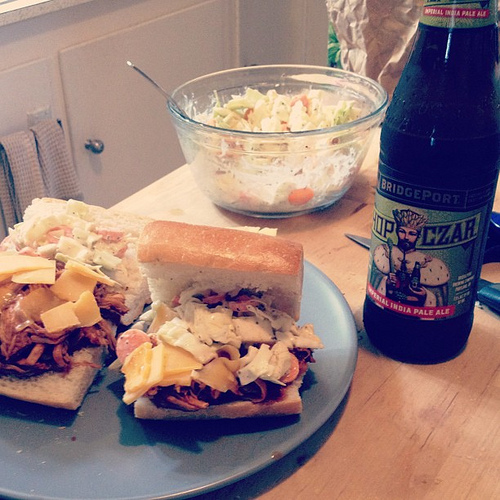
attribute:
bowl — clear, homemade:
[161, 55, 393, 223]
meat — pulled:
[17, 322, 67, 369]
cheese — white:
[112, 333, 209, 405]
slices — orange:
[120, 342, 193, 384]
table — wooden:
[353, 376, 470, 498]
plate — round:
[23, 159, 468, 493]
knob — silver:
[82, 136, 105, 153]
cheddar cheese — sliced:
[124, 350, 198, 387]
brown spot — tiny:
[263, 450, 280, 462]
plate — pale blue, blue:
[0, 254, 361, 499]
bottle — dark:
[359, 2, 496, 365]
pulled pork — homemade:
[1, 238, 324, 400]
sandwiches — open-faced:
[0, 187, 318, 439]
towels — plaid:
[45, 159, 72, 187]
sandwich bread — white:
[131, 213, 309, 325]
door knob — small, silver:
[87, 136, 115, 164]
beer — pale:
[405, 247, 424, 300]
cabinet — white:
[0, 2, 336, 254]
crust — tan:
[136, 216, 308, 294]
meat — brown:
[0, 283, 132, 377]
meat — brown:
[145, 348, 315, 417]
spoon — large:
[122, 54, 192, 122]